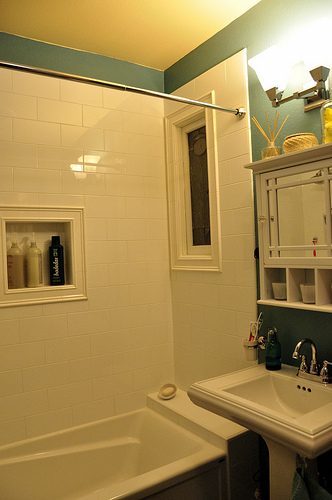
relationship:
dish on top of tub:
[159, 382, 172, 396] [36, 432, 216, 499]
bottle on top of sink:
[251, 119, 287, 159] [195, 375, 319, 452]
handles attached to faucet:
[288, 355, 330, 375] [284, 338, 315, 371]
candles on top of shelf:
[257, 79, 317, 147] [240, 258, 324, 302]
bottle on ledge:
[251, 119, 287, 159] [14, 284, 77, 312]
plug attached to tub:
[123, 467, 139, 479] [36, 432, 216, 499]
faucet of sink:
[284, 338, 315, 371] [195, 375, 319, 452]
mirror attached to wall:
[196, 205, 217, 246] [255, 27, 278, 39]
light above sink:
[256, 45, 285, 85] [195, 375, 319, 452]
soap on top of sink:
[159, 386, 174, 396] [195, 375, 319, 452]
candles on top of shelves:
[257, 79, 317, 147] [262, 214, 325, 293]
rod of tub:
[55, 73, 169, 98] [36, 432, 216, 499]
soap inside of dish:
[159, 386, 174, 396] [159, 382, 172, 396]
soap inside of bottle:
[159, 386, 174, 396] [251, 119, 287, 159]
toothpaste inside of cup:
[239, 318, 265, 350] [244, 340, 257, 365]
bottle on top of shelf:
[251, 119, 287, 159] [240, 258, 324, 302]